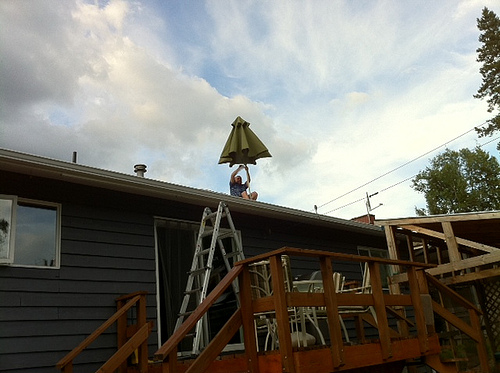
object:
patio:
[128, 246, 441, 373]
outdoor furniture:
[247, 254, 311, 351]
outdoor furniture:
[286, 279, 328, 347]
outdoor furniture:
[324, 261, 378, 342]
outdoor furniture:
[298, 269, 352, 347]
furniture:
[248, 254, 378, 352]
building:
[0, 147, 500, 373]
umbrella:
[218, 115, 272, 199]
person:
[229, 165, 258, 201]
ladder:
[172, 200, 247, 359]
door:
[152, 215, 245, 357]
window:
[0, 194, 62, 270]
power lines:
[342, 119, 500, 207]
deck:
[54, 245, 489, 373]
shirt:
[229, 179, 248, 197]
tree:
[409, 148, 499, 217]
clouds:
[2, 3, 456, 76]